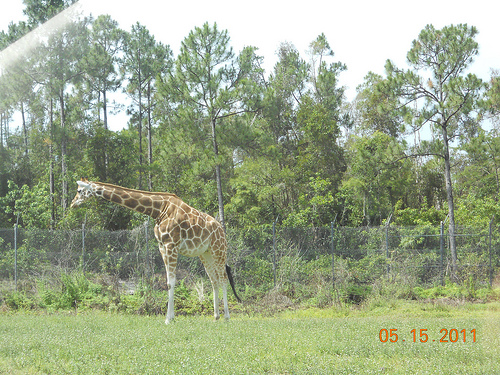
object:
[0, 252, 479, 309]
bush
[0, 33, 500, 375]
area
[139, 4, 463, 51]
sky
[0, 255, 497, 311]
shrubs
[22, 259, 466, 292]
row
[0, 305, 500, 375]
field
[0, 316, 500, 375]
grass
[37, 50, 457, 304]
exhibit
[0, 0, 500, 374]
zoo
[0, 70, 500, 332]
enclosure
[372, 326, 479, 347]
watermark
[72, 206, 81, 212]
nose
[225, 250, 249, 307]
tail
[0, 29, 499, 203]
leaves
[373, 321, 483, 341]
photo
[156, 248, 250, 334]
legs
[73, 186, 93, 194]
eyeball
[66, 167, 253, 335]
animal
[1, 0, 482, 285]
woods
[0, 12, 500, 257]
tree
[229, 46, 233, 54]
needle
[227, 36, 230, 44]
needle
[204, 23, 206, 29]
needle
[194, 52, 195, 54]
needle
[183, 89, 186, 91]
needle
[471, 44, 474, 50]
needle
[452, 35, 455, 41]
needle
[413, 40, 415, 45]
needle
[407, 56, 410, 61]
needle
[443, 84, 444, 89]
needle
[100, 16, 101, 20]
needle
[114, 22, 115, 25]
needle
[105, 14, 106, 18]
needle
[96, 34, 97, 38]
needle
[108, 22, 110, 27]
needle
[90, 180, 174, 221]
neck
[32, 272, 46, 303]
weed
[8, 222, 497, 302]
fence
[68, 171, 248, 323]
giraffe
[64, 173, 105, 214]
head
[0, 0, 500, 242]
trees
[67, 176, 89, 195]
eye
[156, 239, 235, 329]
legs